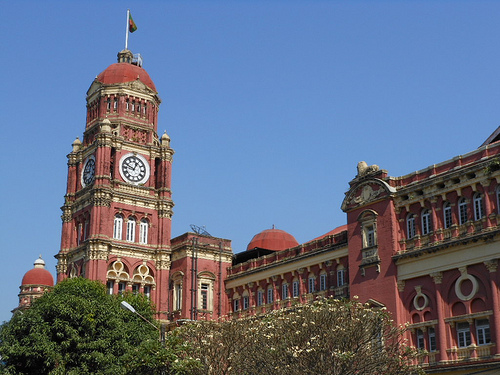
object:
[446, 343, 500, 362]
balcony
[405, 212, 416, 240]
window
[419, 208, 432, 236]
window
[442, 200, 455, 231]
window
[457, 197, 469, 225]
window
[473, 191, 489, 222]
window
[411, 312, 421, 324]
archway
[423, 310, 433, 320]
archway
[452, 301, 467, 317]
archway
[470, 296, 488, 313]
archway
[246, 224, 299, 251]
dome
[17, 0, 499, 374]
building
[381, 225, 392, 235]
brick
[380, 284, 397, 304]
brick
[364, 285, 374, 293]
brick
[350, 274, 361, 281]
brick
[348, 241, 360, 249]
brick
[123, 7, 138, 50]
flag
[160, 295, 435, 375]
flowers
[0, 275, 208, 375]
tree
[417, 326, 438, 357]
window